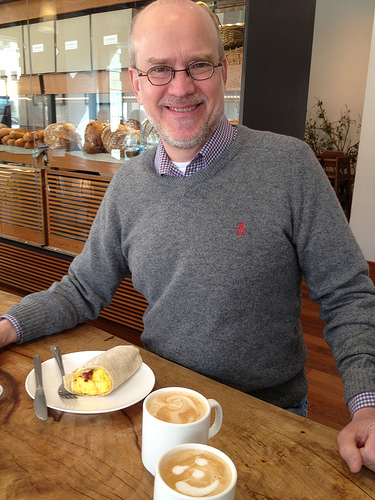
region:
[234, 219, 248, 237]
Red penguin logo on sweater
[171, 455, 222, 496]
White smiley face drawn on the coffee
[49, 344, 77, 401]
Fork sitting on the white plate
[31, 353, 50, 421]
Knife placed next to fork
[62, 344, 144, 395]
Burrito sitting on the white plate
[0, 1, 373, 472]
Man is wearing a gray sweater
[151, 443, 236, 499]
White mug on the table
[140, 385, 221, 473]
White mug next to the white mug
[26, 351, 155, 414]
Round white plate sitting on the table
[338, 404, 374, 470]
Hand placed on the table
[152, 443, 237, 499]
cup of coffee with a smiley face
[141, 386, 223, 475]
white cup of coffee on the table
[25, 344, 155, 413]
burrito on a white plate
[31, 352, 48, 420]
a knife on the edge of a plate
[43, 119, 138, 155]
large loaves of bread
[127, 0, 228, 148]
the man's head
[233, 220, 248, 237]
red logo on the man's sweater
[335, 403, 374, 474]
the man's left hand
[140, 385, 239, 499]
two cups of coffee on the table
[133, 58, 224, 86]
eyeglasses on the man's face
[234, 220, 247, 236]
Red logo on man's shirt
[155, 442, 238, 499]
Happy face on top of drink in coffee mug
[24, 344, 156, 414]
Burrito sitting on white plate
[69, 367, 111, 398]
Scrambled eggs inside burrito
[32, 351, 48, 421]
Knife sitting on side of plate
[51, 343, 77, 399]
Fork sitting on side of white plate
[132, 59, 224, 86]
Glasses on man's face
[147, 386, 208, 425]
Brown and white swirl on top of drink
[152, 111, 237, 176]
Purple and plaid collar on man's shirt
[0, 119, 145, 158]
Baked goods in the window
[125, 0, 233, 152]
this man's smile indicates he is enjoying himself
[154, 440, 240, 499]
the foam on this coffee is smiling as well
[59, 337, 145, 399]
this man is about to eat an egg burrito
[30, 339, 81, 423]
silverware ready to tackle the egg burrito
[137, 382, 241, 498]
two cups indicate the gentleman has a companion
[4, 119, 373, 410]
the gentleman is wearing a natty gray sweater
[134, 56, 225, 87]
the gentleman is wearing glasses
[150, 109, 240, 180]
the man is wearing a checkered shirt under his sweater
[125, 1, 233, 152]
the gentleman is bald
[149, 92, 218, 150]
the gentleman sports a mustache and beard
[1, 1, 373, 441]
person standing near a table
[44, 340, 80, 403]
fork on a white plate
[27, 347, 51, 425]
knife on a plate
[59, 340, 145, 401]
food on a plate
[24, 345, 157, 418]
white plate on a table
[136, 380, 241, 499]
two white cups on a table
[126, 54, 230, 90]
glasses on a persons face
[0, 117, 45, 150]
bread on a shelf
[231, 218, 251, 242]
logo on a sweater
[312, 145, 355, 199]
wooden high chair near a wall